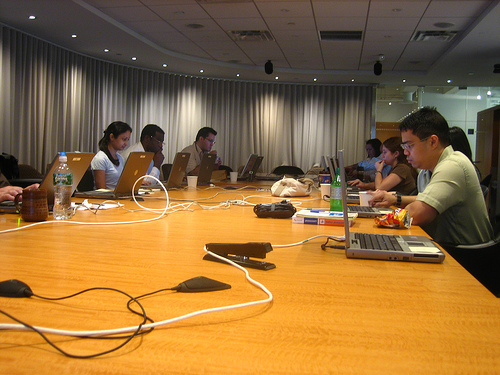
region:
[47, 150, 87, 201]
lap top on table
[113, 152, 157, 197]
lap top on table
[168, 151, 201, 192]
lap top on table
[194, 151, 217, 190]
lap top on table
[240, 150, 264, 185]
lap top on table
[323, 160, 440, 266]
lap top on table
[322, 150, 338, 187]
lap top on table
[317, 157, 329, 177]
lap top on table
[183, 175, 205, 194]
cup of coffee on desk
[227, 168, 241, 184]
cup of coffee on desk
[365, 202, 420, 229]
The bag of chips is open.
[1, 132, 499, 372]
The table is wood.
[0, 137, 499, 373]
The table is long.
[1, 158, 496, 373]
The table is wide.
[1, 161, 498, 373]
The table is rectangular.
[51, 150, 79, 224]
Bottle of water on a table.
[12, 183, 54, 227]
The coffee cup is brown.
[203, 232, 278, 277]
The stapler is brown.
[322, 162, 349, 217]
A green soda bottle.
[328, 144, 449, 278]
The laptop is open.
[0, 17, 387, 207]
the round-edged white curtain of a conference room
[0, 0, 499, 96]
inset round ceiling lights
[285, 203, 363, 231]
book stacked beneath notep0ad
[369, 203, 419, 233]
cheetos or fritos, open little foil bag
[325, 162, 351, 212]
small bottle, 5/6ths empty, of sprite, i think diet sprite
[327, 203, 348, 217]
sprite left in the sprite bottle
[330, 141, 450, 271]
laptop, silver, fairly heavy, unattended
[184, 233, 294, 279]
black stapler wrapped in white ethernet cable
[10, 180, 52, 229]
coffee mug, striped in variegated brown shades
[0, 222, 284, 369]
two black mice, one interestingly shaped, tangled around a white ethernet cable which has also ensnared the stapler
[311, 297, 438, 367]
The table is made of wood.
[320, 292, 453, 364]
The table is yellow.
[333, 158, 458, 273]
A laptop.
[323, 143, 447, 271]
The laptop is gray.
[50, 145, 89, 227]
A plastic water bottle.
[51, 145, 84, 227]
The water bottle is clear.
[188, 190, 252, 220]
A lot of wires.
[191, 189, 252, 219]
The wires are white.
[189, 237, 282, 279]
A stapler.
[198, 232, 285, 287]
The stapler is black.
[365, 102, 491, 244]
Man is wearing green shirt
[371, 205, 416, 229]
Bag of chips by man in green shirt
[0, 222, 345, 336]
White cord on black stapler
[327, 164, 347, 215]
Green soda bottle near bag of chips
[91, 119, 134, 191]
Woman using laptop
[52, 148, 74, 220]
Clear water bottle next to brown mug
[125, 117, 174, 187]
Man wearing eye glasses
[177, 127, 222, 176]
Man wearing eye glasses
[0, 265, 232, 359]
Black cord tangled on white cord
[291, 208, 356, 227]
Book by green soda bottle